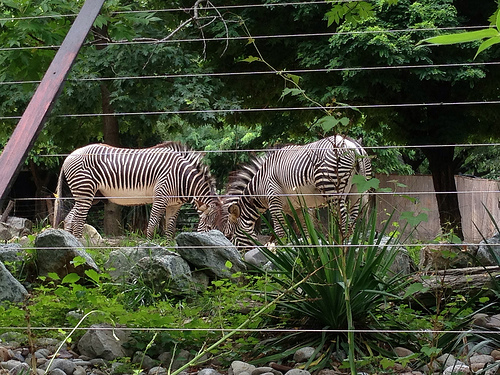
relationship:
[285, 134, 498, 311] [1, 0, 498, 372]
flower near fence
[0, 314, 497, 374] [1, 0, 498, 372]
gravel near fence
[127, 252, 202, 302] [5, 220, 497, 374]
rock on ground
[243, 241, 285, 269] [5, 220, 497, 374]
rock on ground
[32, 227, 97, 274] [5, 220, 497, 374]
rock on ground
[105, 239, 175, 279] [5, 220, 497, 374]
rock on ground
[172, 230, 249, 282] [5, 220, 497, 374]
rock on ground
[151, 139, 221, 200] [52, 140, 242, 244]
mane on zebra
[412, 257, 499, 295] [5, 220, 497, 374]
log on ground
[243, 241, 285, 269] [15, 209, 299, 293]
rock on ground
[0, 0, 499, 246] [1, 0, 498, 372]
trees front fence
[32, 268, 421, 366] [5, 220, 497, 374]
grass on ground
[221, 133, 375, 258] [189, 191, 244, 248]
zebra has head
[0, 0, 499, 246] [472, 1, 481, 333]
trees front fence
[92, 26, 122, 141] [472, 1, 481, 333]
trees front fence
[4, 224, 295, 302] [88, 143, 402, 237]
rocks front zebra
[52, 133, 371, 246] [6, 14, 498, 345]
zebras front fence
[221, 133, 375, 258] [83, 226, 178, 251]
zebra eat grass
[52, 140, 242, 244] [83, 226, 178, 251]
zebra eat grass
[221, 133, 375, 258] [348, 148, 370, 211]
zebra has tail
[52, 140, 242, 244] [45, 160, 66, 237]
zebra has tail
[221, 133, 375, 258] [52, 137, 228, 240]
zebra looking zebra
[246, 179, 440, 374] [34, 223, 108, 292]
bush near rock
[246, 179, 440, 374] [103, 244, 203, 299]
bush near rock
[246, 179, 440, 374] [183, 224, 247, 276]
bush near rock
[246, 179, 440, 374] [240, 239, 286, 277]
bush near rock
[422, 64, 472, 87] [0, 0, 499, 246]
leaves on tree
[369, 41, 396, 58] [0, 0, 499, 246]
leaves on tree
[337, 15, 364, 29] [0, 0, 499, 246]
leaves on tree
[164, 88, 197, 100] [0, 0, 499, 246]
leaves on tree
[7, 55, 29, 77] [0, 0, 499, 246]
leaves on tree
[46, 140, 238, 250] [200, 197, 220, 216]
zebra has ear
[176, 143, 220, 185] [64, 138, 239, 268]
mane on zebra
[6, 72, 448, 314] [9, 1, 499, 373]
zebras in zoo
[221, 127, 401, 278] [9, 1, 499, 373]
zebra in zoo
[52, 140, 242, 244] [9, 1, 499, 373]
zebra in zoo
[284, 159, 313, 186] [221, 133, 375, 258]
stripes on zebra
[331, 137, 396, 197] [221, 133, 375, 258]
tail on zebra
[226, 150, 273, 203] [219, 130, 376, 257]
mane on zebra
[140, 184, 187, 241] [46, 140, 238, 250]
legs under zebra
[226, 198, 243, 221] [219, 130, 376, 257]
ear on zebra